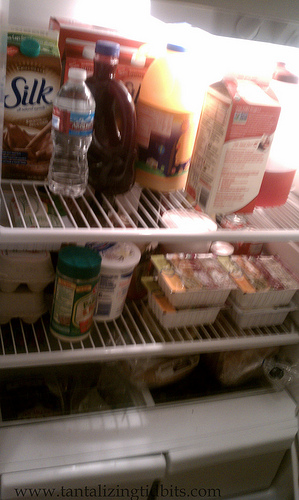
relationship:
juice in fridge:
[133, 38, 209, 196] [4, 2, 298, 348]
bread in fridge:
[115, 337, 286, 388] [3, 1, 297, 495]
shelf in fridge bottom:
[1, 354, 276, 415] [1, 375, 296, 498]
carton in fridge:
[165, 420, 298, 498] [8, 10, 271, 498]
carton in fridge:
[2, 23, 64, 185] [3, 1, 297, 495]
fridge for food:
[3, 1, 297, 495] [11, 210, 288, 340]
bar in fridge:
[5, 165, 293, 362] [3, 1, 297, 495]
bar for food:
[5, 165, 293, 362] [2, 17, 297, 424]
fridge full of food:
[3, 1, 297, 495] [46, 241, 131, 355]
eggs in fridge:
[1, 251, 55, 292] [3, 1, 297, 495]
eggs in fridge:
[0, 251, 55, 326] [3, 1, 297, 495]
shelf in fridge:
[1, 180, 298, 415] [16, 71, 287, 498]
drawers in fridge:
[0, 424, 299, 499] [3, 1, 297, 495]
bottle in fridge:
[45, 65, 97, 198] [3, 1, 297, 495]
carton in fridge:
[184, 74, 285, 216] [3, 1, 297, 495]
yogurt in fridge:
[90, 242, 141, 323] [3, 1, 297, 495]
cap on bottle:
[167, 44, 186, 50] [133, 40, 204, 190]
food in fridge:
[149, 246, 296, 328] [3, 1, 297, 495]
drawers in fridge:
[6, 372, 291, 498] [3, 1, 297, 495]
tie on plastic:
[259, 354, 267, 369] [211, 354, 296, 399]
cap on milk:
[17, 36, 42, 57] [218, 90, 296, 247]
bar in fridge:
[5, 165, 293, 362] [5, 4, 297, 447]